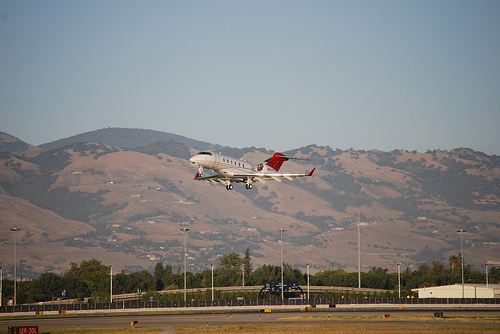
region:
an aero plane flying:
[169, 128, 369, 248]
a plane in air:
[173, 138, 338, 228]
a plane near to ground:
[155, 131, 435, 258]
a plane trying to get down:
[156, 125, 361, 227]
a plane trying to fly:
[168, 118, 388, 264]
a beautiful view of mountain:
[7, 122, 497, 272]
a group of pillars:
[39, 258, 488, 303]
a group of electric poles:
[41, 238, 472, 313]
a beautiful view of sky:
[11, 13, 471, 153]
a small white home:
[396, 238, 497, 309]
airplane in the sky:
[180, 141, 320, 191]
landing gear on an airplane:
[220, 176, 238, 193]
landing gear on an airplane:
[240, 175, 255, 192]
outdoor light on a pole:
[272, 222, 293, 306]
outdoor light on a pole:
[177, 220, 193, 307]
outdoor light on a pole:
[3, 223, 27, 322]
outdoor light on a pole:
[454, 226, 473, 301]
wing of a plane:
[227, 163, 319, 188]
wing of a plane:
[190, 168, 225, 188]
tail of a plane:
[253, 148, 313, 173]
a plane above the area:
[176, 128, 326, 208]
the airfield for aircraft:
[21, 234, 473, 331]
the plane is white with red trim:
[168, 125, 337, 195]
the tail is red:
[252, 133, 289, 174]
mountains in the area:
[17, 117, 482, 237]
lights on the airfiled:
[90, 240, 231, 315]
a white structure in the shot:
[405, 255, 492, 307]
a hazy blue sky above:
[44, 31, 406, 110]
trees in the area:
[42, 230, 439, 314]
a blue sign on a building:
[254, 272, 305, 296]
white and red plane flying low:
[176, 144, 316, 194]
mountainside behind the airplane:
[5, 122, 499, 285]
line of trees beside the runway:
[14, 253, 489, 287]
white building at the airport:
[411, 288, 499, 305]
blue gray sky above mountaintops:
[5, 4, 495, 145]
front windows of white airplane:
[197, 149, 212, 158]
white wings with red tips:
[190, 170, 320, 183]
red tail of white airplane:
[265, 152, 290, 169]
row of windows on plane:
[222, 153, 245, 171]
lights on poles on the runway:
[5, 218, 499, 312]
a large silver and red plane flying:
[188, 128, 316, 200]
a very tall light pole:
[276, 220, 291, 311]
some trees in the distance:
[323, 269, 416, 289]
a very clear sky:
[20, 5, 460, 122]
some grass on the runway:
[231, 325, 277, 332]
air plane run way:
[16, 313, 268, 325]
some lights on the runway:
[118, 313, 142, 332]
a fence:
[8, 298, 241, 316]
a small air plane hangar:
[408, 283, 499, 301]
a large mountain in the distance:
[65, 125, 177, 151]